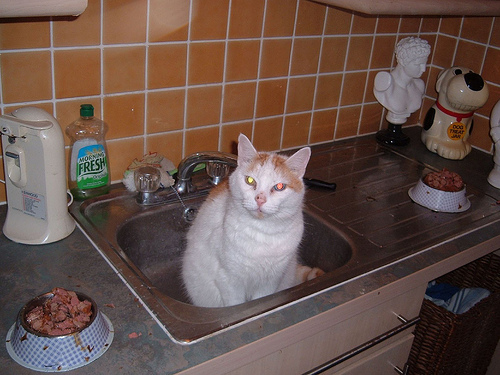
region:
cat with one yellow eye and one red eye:
[185, 133, 318, 308]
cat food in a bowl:
[3, 288, 117, 373]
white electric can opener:
[1, 105, 79, 247]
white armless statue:
[374, 33, 432, 127]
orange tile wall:
[5, 6, 496, 171]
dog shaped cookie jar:
[420, 58, 491, 161]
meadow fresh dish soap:
[63, 102, 113, 206]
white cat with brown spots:
[185, 131, 314, 306]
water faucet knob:
[131, 165, 163, 209]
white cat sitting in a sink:
[112, 131, 346, 306]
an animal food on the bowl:
[5, 277, 117, 374]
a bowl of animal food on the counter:
[403, 164, 475, 216]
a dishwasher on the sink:
[63, 100, 117, 204]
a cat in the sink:
[186, 125, 356, 312]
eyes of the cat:
[237, 172, 289, 192]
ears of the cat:
[233, 132, 312, 167]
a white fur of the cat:
[204, 225, 274, 272]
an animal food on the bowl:
[47, 301, 74, 326]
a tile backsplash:
[156, 63, 350, 131]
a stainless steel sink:
[308, 193, 370, 266]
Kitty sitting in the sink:
[124, 129, 343, 324]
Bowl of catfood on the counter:
[3, 282, 116, 373]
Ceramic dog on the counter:
[422, 61, 493, 163]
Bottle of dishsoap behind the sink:
[65, 99, 116, 201]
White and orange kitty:
[180, 131, 336, 310]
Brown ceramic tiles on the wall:
[88, 1, 428, 169]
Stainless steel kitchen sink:
[55, 117, 499, 337]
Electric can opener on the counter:
[0, 99, 80, 249]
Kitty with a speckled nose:
[252, 190, 267, 205]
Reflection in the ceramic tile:
[87, 0, 214, 76]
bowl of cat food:
[4, 277, 114, 373]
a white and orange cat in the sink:
[187, 133, 328, 315]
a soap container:
[65, 100, 112, 201]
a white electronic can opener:
[4, 99, 72, 254]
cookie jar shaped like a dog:
[422, 66, 492, 160]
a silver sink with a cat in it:
[82, 148, 350, 338]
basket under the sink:
[411, 259, 496, 373]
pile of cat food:
[25, 288, 95, 338]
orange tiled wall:
[5, 0, 496, 190]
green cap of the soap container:
[70, 98, 102, 123]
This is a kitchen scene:
[2, 5, 495, 370]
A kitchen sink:
[71, 132, 361, 346]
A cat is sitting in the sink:
[72, 130, 368, 340]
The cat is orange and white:
[181, 132, 323, 308]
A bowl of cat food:
[4, 285, 116, 373]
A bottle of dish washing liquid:
[65, 100, 112, 199]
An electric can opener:
[0, 105, 77, 245]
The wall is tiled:
[1, 0, 498, 200]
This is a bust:
[372, 34, 432, 148]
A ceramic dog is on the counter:
[420, 64, 490, 162]